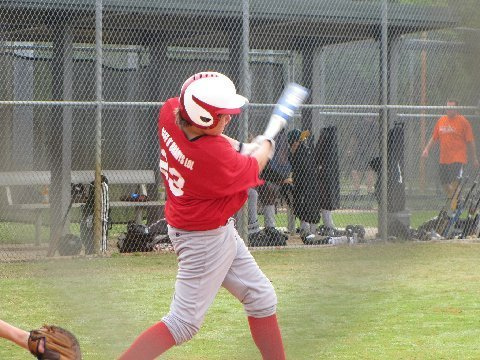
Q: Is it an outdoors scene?
A: Yes, it is outdoors.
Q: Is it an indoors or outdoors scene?
A: It is outdoors.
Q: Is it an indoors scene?
A: No, it is outdoors.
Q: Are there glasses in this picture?
A: No, there are no glasses.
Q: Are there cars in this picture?
A: No, there are no cars.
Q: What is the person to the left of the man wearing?
A: The person is wearing a shirt.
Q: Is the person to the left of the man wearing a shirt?
A: Yes, the person is wearing a shirt.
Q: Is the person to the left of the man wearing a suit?
A: No, the person is wearing a shirt.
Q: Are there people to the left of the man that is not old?
A: Yes, there is a person to the left of the man.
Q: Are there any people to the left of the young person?
A: Yes, there is a person to the left of the man.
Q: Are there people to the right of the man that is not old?
A: No, the person is to the left of the man.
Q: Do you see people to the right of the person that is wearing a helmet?
A: No, the person is to the left of the man.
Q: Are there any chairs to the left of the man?
A: No, there is a person to the left of the man.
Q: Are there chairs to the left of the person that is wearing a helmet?
A: No, there is a person to the left of the man.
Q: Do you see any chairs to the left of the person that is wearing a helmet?
A: No, there is a person to the left of the man.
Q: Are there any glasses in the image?
A: No, there are no glasses.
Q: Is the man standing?
A: Yes, the man is standing.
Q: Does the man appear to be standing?
A: Yes, the man is standing.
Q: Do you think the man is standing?
A: Yes, the man is standing.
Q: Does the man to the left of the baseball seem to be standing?
A: Yes, the man is standing.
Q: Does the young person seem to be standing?
A: Yes, the man is standing.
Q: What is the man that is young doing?
A: The man is standing.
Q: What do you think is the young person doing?
A: The man is standing.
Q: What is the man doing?
A: The man is standing.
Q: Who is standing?
A: The man is standing.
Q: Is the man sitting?
A: No, the man is standing.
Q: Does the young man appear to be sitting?
A: No, the man is standing.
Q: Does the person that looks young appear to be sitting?
A: No, the man is standing.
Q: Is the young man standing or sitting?
A: The man is standing.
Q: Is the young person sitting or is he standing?
A: The man is standing.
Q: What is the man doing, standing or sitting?
A: The man is standing.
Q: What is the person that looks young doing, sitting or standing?
A: The man is standing.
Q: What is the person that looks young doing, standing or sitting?
A: The man is standing.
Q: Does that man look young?
A: Yes, the man is young.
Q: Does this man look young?
A: Yes, the man is young.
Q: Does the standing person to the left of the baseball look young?
A: Yes, the man is young.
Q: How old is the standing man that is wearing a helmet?
A: The man is young.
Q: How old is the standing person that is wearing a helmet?
A: The man is young.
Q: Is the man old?
A: No, the man is young.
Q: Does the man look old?
A: No, the man is young.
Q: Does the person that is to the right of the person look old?
A: No, the man is young.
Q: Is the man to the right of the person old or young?
A: The man is young.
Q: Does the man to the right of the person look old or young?
A: The man is young.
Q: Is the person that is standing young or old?
A: The man is young.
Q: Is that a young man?
A: Yes, that is a young man.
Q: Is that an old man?
A: No, that is a young man.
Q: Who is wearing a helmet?
A: The man is wearing a helmet.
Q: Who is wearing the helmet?
A: The man is wearing a helmet.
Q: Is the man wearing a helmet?
A: Yes, the man is wearing a helmet.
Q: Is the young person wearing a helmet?
A: Yes, the man is wearing a helmet.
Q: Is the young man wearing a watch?
A: No, the man is wearing a helmet.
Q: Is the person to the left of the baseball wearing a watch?
A: No, the man is wearing a helmet.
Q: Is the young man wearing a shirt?
A: Yes, the man is wearing a shirt.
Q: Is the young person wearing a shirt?
A: Yes, the man is wearing a shirt.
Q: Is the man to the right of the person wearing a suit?
A: No, the man is wearing a shirt.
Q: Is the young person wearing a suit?
A: No, the man is wearing a shirt.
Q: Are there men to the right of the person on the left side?
A: Yes, there is a man to the right of the person.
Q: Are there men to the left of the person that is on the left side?
A: No, the man is to the right of the person.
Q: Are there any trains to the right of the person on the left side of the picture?
A: No, there is a man to the right of the person.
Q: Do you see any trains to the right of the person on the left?
A: No, there is a man to the right of the person.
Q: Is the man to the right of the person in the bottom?
A: Yes, the man is to the right of the person.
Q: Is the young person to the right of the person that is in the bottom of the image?
A: Yes, the man is to the right of the person.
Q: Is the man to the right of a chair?
A: No, the man is to the right of the person.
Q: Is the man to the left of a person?
A: No, the man is to the right of a person.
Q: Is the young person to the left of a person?
A: No, the man is to the right of a person.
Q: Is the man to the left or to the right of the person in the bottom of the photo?
A: The man is to the right of the person.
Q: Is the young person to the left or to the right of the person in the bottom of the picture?
A: The man is to the right of the person.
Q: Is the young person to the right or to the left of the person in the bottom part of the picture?
A: The man is to the right of the person.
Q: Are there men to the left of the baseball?
A: Yes, there is a man to the left of the baseball.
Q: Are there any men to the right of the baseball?
A: No, the man is to the left of the baseball.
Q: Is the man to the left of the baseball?
A: Yes, the man is to the left of the baseball.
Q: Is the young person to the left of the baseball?
A: Yes, the man is to the left of the baseball.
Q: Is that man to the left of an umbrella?
A: No, the man is to the left of the baseball.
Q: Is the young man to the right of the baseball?
A: No, the man is to the left of the baseball.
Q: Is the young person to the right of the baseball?
A: No, the man is to the left of the baseball.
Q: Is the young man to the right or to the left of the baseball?
A: The man is to the left of the baseball.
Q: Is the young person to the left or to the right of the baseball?
A: The man is to the left of the baseball.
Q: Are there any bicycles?
A: No, there are no bicycles.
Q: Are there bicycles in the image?
A: No, there are no bicycles.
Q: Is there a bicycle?
A: No, there are no bicycles.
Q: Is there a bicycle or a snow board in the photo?
A: No, there are no bicycles or snowboards.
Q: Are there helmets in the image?
A: Yes, there is a helmet.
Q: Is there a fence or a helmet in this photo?
A: Yes, there is a helmet.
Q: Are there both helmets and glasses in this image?
A: No, there is a helmet but no glasses.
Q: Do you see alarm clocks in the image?
A: No, there are no alarm clocks.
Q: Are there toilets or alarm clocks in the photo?
A: No, there are no alarm clocks or toilets.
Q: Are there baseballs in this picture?
A: Yes, there is a baseball.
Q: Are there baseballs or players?
A: Yes, there is a baseball.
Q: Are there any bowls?
A: No, there are no bowls.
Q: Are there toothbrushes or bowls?
A: No, there are no bowls or toothbrushes.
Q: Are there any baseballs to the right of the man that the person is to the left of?
A: Yes, there is a baseball to the right of the man.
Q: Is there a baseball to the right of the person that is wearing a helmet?
A: Yes, there is a baseball to the right of the man.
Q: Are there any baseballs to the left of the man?
A: No, the baseball is to the right of the man.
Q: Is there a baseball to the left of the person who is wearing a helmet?
A: No, the baseball is to the right of the man.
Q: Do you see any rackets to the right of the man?
A: No, there is a baseball to the right of the man.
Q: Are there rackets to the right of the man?
A: No, there is a baseball to the right of the man.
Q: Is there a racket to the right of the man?
A: No, there is a baseball to the right of the man.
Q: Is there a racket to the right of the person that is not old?
A: No, there is a baseball to the right of the man.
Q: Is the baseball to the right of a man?
A: Yes, the baseball is to the right of a man.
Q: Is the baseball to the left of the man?
A: No, the baseball is to the right of the man.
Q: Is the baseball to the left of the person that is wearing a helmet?
A: No, the baseball is to the right of the man.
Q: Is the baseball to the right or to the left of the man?
A: The baseball is to the right of the man.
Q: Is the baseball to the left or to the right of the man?
A: The baseball is to the right of the man.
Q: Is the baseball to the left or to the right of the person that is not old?
A: The baseball is to the right of the man.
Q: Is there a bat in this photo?
A: Yes, there is a bat.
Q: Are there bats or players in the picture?
A: Yes, there is a bat.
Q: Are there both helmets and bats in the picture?
A: Yes, there are both a bat and a helmet.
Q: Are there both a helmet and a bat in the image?
A: Yes, there are both a bat and a helmet.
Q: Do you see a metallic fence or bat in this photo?
A: Yes, there is a metal bat.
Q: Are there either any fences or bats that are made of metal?
A: Yes, the bat is made of metal.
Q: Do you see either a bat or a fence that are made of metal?
A: Yes, the bat is made of metal.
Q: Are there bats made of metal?
A: Yes, there is a bat that is made of metal.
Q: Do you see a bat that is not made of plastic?
A: Yes, there is a bat that is made of metal.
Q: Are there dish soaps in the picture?
A: No, there are no dish soaps.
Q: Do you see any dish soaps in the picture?
A: No, there are no dish soaps.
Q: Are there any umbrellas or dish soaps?
A: No, there are no dish soaps or umbrellas.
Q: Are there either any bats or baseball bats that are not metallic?
A: No, there is a bat but it is metallic.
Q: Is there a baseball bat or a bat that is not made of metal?
A: No, there is a bat but it is made of metal.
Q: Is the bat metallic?
A: Yes, the bat is metallic.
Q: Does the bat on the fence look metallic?
A: Yes, the bat is metallic.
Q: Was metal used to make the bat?
A: Yes, the bat is made of metal.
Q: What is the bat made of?
A: The bat is made of metal.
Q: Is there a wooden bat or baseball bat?
A: No, there is a bat but it is metallic.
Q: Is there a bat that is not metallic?
A: No, there is a bat but it is metallic.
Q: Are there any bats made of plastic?
A: No, there is a bat but it is made of metal.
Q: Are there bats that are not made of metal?
A: No, there is a bat but it is made of metal.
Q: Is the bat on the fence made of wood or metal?
A: The bat is made of metal.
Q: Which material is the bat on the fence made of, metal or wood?
A: The bat is made of metal.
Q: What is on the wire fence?
A: The bat is on the fence.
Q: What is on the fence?
A: The bat is on the fence.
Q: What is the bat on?
A: The bat is on the fence.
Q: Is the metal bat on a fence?
A: Yes, the bat is on a fence.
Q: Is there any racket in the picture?
A: No, there are no rackets.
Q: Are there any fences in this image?
A: Yes, there is a fence.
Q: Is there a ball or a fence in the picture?
A: Yes, there is a fence.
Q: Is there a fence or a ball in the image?
A: Yes, there is a fence.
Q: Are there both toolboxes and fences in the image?
A: No, there is a fence but no toolboxes.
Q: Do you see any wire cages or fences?
A: Yes, there is a wire fence.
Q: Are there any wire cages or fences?
A: Yes, there is a wire fence.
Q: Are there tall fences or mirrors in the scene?
A: Yes, there is a tall fence.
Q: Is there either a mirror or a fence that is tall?
A: Yes, the fence is tall.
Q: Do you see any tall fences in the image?
A: Yes, there is a tall fence.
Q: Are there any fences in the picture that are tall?
A: Yes, there is a fence that is tall.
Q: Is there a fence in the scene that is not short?
A: Yes, there is a tall fence.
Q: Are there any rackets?
A: No, there are no rackets.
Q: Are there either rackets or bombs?
A: No, there are no rackets or bombs.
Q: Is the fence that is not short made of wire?
A: Yes, the fence is made of wire.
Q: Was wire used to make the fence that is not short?
A: Yes, the fence is made of wire.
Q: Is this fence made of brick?
A: No, the fence is made of wire.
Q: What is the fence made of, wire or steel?
A: The fence is made of wire.